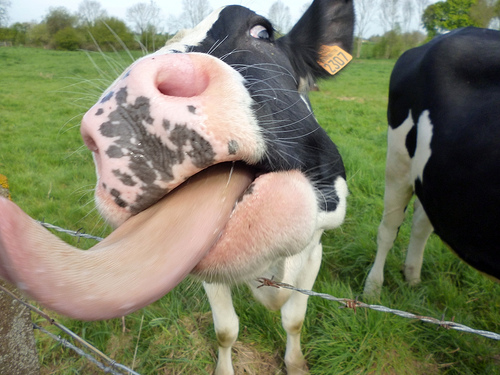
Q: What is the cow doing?
A: Sticking out it's tongue.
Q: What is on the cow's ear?
A: A tag.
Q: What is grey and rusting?
A: Fence.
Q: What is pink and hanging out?
A: Tongue.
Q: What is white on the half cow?
A: Legs.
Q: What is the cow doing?
A: Sticking out its tongue.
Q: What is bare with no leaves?
A: Trees.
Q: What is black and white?
A: Cows.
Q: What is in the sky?
A: Nothing.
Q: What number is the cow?
A: 2307.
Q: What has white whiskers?
A: Cow.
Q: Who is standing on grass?
A: The cows.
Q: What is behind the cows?
A: Trees.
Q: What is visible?
A: A tongue.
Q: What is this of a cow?
A: Tongue.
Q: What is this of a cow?
A: A leg.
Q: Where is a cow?
A: Field.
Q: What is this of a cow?
A: The tongue.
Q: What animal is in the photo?
A: Cow.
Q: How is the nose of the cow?
A: Mottled.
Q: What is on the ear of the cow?
A: Tag.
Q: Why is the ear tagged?
A: Identification.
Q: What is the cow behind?
A: Barbed wire.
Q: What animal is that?
A: A cow.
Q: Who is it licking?
A: The photographer.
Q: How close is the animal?
A: Enough to get the camera licked.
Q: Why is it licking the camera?
A: The camera is close to its mouth.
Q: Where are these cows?
A: On an open field.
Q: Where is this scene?
A: On a ranch.